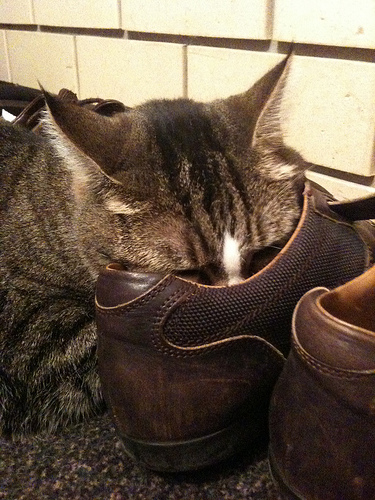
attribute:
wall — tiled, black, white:
[3, 0, 374, 210]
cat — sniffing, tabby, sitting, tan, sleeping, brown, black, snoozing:
[5, 39, 309, 448]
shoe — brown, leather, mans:
[91, 183, 374, 475]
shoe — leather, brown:
[263, 251, 373, 497]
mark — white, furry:
[219, 229, 245, 277]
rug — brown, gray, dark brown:
[4, 411, 281, 499]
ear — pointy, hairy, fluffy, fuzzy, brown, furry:
[36, 80, 121, 196]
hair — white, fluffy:
[41, 112, 105, 188]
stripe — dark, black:
[153, 108, 195, 222]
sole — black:
[117, 409, 270, 476]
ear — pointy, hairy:
[231, 38, 297, 165]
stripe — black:
[208, 122, 259, 236]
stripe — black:
[190, 214, 217, 262]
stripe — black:
[7, 286, 84, 352]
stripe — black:
[28, 313, 92, 384]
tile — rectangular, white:
[74, 31, 188, 113]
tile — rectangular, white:
[187, 43, 374, 181]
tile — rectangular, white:
[5, 28, 83, 101]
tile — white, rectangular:
[120, 2, 274, 44]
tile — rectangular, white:
[274, 2, 373, 56]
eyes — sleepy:
[165, 237, 285, 280]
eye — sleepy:
[169, 264, 211, 280]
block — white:
[1, 2, 37, 29]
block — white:
[32, 0, 123, 31]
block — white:
[294, 167, 374, 210]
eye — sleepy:
[252, 239, 283, 260]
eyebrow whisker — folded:
[254, 240, 288, 253]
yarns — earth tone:
[27, 436, 121, 481]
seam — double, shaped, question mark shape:
[146, 284, 231, 360]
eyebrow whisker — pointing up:
[272, 153, 327, 201]